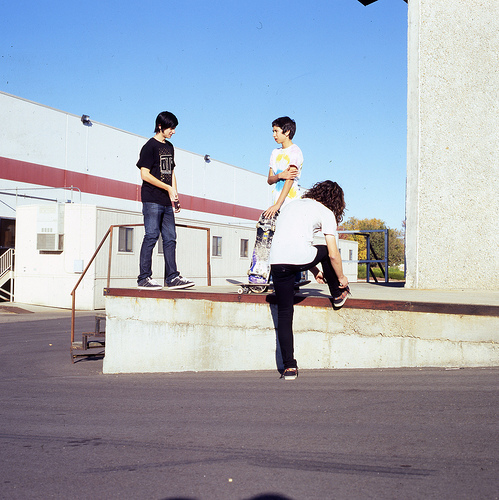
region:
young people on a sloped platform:
[107, 92, 406, 376]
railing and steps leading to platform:
[59, 220, 208, 359]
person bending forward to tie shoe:
[301, 178, 348, 307]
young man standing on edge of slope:
[136, 106, 191, 290]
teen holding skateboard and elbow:
[237, 113, 299, 281]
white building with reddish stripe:
[17, 97, 360, 298]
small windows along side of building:
[99, 225, 355, 258]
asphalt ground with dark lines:
[25, 378, 448, 489]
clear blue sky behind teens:
[131, 14, 347, 135]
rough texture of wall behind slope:
[405, 12, 493, 284]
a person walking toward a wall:
[99, 85, 204, 299]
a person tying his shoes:
[260, 163, 374, 416]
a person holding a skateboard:
[250, 108, 309, 309]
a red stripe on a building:
[5, 156, 360, 236]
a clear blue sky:
[39, 15, 409, 221]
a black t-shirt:
[131, 131, 200, 216]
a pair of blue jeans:
[131, 184, 191, 289]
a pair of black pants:
[253, 236, 357, 382]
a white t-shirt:
[258, 189, 349, 274]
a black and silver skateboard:
[248, 191, 305, 327]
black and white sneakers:
[136, 275, 195, 292]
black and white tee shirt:
[140, 139, 177, 200]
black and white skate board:
[249, 209, 276, 293]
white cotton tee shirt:
[278, 198, 331, 262]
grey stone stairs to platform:
[65, 306, 115, 363]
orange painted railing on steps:
[68, 222, 214, 333]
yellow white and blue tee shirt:
[270, 145, 302, 199]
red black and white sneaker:
[273, 355, 302, 383]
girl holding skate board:
[257, 112, 304, 292]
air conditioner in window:
[35, 231, 64, 255]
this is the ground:
[115, 390, 206, 457]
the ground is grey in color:
[125, 386, 216, 451]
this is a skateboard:
[239, 205, 271, 291]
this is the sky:
[354, 34, 393, 210]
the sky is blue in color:
[103, 10, 271, 51]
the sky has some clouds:
[353, 184, 392, 218]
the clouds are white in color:
[351, 192, 389, 214]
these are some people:
[128, 100, 355, 368]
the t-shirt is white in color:
[280, 222, 315, 253]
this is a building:
[0, 138, 116, 314]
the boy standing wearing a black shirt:
[135, 109, 195, 290]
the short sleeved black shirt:
[136, 135, 179, 204]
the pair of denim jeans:
[137, 192, 180, 280]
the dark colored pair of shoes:
[134, 274, 194, 290]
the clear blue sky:
[6, 4, 415, 217]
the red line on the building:
[1, 157, 270, 221]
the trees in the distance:
[337, 212, 406, 262]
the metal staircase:
[70, 303, 107, 370]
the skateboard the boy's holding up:
[247, 209, 274, 293]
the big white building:
[3, 88, 355, 308]